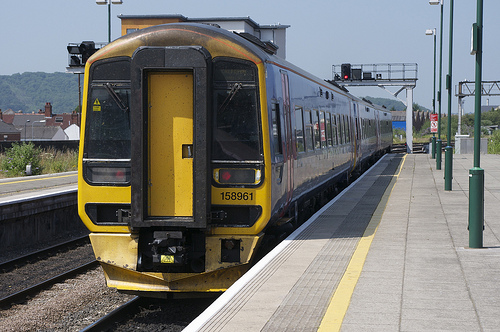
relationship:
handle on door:
[181, 142, 197, 159] [145, 69, 196, 216]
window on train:
[86, 67, 129, 162] [64, 25, 393, 316]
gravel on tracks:
[28, 298, 109, 323] [2, 248, 184, 330]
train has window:
[64, 25, 393, 316] [86, 67, 129, 162]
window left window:
[83, 80, 129, 162] [86, 67, 129, 162]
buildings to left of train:
[0, 103, 80, 152] [2, 52, 87, 249]